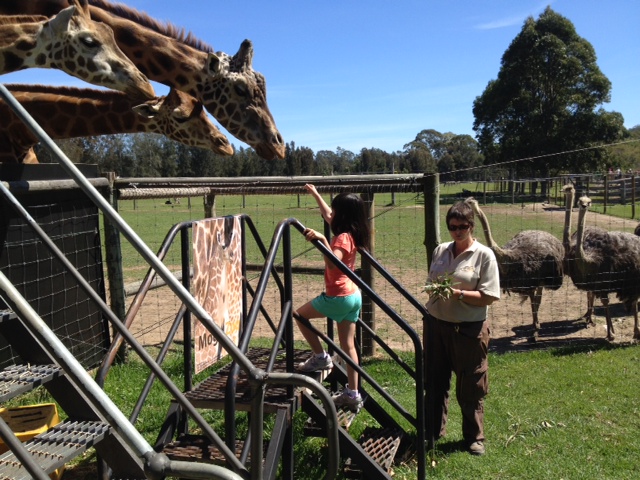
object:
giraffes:
[0, 0, 285, 164]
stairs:
[184, 346, 402, 473]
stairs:
[149, 433, 269, 479]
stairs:
[0, 307, 109, 478]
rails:
[322, 215, 431, 429]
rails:
[282, 218, 426, 480]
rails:
[224, 218, 294, 466]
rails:
[94, 221, 192, 425]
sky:
[0, 0, 640, 153]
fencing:
[0, 189, 111, 372]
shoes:
[424, 438, 485, 454]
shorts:
[311, 287, 362, 322]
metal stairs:
[0, 84, 342, 480]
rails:
[94, 215, 429, 480]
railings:
[0, 173, 640, 372]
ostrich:
[465, 184, 640, 341]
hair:
[446, 202, 475, 228]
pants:
[422, 312, 490, 439]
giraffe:
[0, 83, 234, 165]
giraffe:
[0, 0, 154, 98]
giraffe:
[0, 0, 286, 159]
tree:
[472, 5, 624, 198]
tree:
[438, 134, 487, 182]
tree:
[402, 142, 437, 174]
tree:
[314, 150, 337, 176]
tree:
[359, 146, 389, 175]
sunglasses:
[447, 223, 472, 232]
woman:
[421, 201, 500, 455]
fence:
[116, 174, 639, 348]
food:
[421, 271, 462, 301]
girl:
[295, 183, 368, 403]